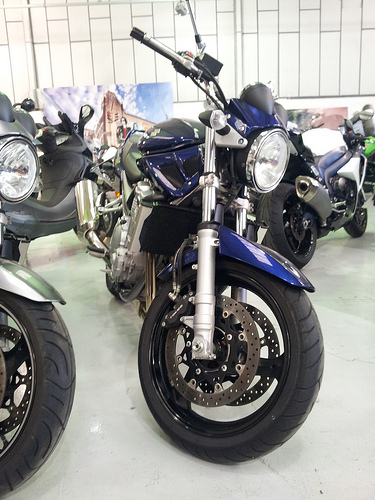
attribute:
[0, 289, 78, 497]
front tire — black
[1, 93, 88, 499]
motorcycle — black, white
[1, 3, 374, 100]
window — white, tall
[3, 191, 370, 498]
floor — gray, pavement, dirty, white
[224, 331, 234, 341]
bolt — metal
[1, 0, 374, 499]
bikes — parked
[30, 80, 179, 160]
painting — illustration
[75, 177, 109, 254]
pipe — chrome, silver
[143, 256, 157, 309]
shock — silver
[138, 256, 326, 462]
tire — rubber, rubbber, black, new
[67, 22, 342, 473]
motorcycle — shiny blue, blue